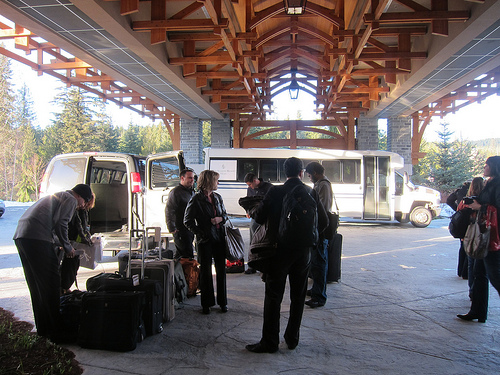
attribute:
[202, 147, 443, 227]
ride — blue, white, parked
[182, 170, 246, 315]
person — standing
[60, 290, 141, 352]
luggage — on the ground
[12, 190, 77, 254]
shirt — gray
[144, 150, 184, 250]
door — open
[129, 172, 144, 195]
tail-light — red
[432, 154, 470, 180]
leaves — green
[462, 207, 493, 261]
bag — grey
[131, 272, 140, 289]
tag — white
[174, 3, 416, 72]
ceiling rafters — brown, metal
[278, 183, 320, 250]
backpack — black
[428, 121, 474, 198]
tree — green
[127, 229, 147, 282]
handle of suitcase — up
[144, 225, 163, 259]
handle of suitcase — up